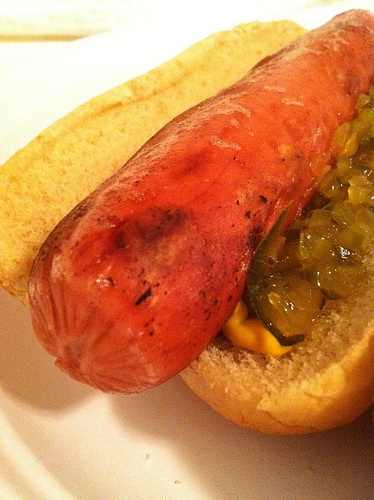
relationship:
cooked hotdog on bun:
[28, 8, 374, 383] [0, 21, 372, 433]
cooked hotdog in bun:
[28, 8, 374, 383] [0, 20, 305, 294]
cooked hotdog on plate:
[28, 8, 374, 383] [0, 0, 373, 496]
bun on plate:
[3, 0, 374, 440] [0, 0, 373, 496]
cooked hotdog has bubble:
[28, 8, 374, 383] [276, 80, 307, 117]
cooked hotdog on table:
[28, 8, 374, 383] [0, 0, 372, 498]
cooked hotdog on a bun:
[49, 112, 263, 343] [9, 29, 264, 182]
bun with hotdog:
[3, 0, 374, 440] [213, 141, 278, 200]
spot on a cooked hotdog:
[254, 192, 272, 207] [28, 8, 374, 383]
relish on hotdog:
[245, 77, 373, 348] [77, 58, 371, 315]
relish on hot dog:
[245, 77, 373, 348] [33, 13, 369, 297]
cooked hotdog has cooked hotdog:
[28, 8, 374, 383] [28, 8, 374, 383]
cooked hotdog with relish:
[28, 8, 374, 383] [245, 77, 373, 348]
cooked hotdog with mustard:
[28, 8, 374, 383] [220, 295, 293, 357]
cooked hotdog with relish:
[28, 8, 374, 383] [262, 192, 355, 343]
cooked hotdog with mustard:
[28, 8, 374, 383] [222, 305, 273, 355]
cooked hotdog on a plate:
[28, 8, 374, 383] [0, 22, 157, 121]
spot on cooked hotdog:
[128, 141, 374, 344] [28, 8, 374, 383]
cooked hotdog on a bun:
[28, 8, 374, 383] [0, 21, 372, 433]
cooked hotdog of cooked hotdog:
[28, 8, 374, 383] [28, 8, 374, 383]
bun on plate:
[3, 11, 290, 180] [7, 14, 369, 96]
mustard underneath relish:
[220, 295, 293, 357] [245, 77, 373, 348]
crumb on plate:
[268, 436, 369, 488] [5, 25, 341, 487]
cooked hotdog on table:
[28, 8, 374, 383] [5, 14, 360, 390]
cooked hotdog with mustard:
[28, 8, 374, 383] [219, 285, 297, 357]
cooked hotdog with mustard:
[28, 8, 374, 383] [220, 279, 311, 357]